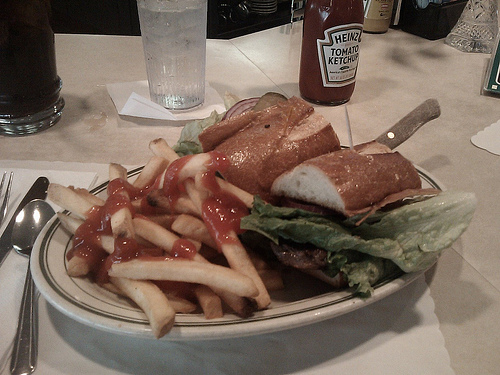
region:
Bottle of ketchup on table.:
[287, 27, 415, 137]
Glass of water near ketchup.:
[129, 25, 248, 99]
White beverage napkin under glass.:
[109, 75, 228, 149]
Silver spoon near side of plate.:
[13, 191, 58, 370]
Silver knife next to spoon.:
[15, 171, 36, 241]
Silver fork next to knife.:
[1, 165, 31, 226]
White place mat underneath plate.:
[50, 143, 265, 370]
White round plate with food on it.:
[67, 167, 347, 361]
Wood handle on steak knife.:
[381, 90, 453, 162]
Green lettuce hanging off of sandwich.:
[303, 206, 434, 286]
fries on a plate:
[65, 146, 260, 284]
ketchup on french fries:
[111, 181, 137, 207]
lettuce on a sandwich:
[382, 190, 482, 230]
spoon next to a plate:
[13, 190, 34, 362]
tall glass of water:
[141, 0, 212, 112]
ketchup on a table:
[301, 0, 378, 100]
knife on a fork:
[392, 86, 463, 151]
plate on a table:
[250, 303, 322, 333]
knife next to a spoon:
[31, 170, 54, 191]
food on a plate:
[96, 98, 474, 294]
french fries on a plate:
[2, 78, 491, 340]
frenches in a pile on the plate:
[40, 72, 407, 347]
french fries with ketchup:
[26, 50, 307, 374]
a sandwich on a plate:
[157, 48, 474, 328]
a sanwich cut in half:
[180, 71, 476, 323]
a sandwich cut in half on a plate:
[29, 28, 412, 373]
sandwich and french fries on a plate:
[59, 57, 487, 364]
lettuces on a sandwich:
[167, 40, 489, 329]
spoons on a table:
[12, 161, 100, 373]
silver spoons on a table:
[5, 168, 99, 374]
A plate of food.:
[34, 87, 477, 367]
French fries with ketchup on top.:
[46, 139, 271, 330]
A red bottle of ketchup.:
[301, 1, 366, 106]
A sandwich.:
[201, 101, 429, 293]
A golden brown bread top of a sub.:
[201, 99, 423, 206]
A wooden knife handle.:
[373, 96, 442, 153]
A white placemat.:
[1, 157, 457, 372]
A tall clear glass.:
[134, 0, 208, 108]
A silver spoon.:
[8, 200, 55, 373]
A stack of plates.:
[254, 0, 279, 18]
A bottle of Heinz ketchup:
[291, 2, 385, 109]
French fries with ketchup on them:
[38, 130, 274, 335]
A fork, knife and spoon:
[2, 157, 65, 374]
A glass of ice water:
[127, 3, 235, 113]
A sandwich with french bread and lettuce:
[174, 95, 461, 300]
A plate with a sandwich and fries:
[21, 85, 468, 365]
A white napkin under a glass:
[92, 63, 238, 138]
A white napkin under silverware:
[3, 144, 104, 371]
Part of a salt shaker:
[441, 1, 498, 56]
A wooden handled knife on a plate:
[326, 90, 456, 166]